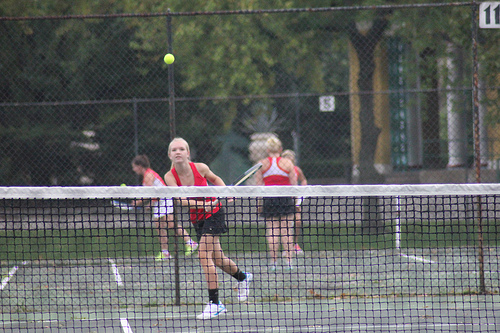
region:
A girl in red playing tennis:
[163, 136, 253, 319]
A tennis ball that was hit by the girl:
[162, 52, 174, 65]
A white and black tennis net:
[1, 182, 499, 332]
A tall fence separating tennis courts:
[2, 1, 499, 307]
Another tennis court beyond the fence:
[1, 243, 498, 308]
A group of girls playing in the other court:
[108, 135, 305, 272]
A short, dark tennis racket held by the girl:
[201, 165, 263, 213]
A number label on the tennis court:
[478, 1, 498, 29]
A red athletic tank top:
[169, 161, 223, 222]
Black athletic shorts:
[190, 205, 230, 241]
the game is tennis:
[9, 15, 488, 327]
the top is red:
[158, 161, 227, 217]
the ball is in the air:
[143, 45, 180, 72]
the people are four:
[122, 114, 324, 283]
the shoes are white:
[200, 268, 260, 327]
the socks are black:
[200, 271, 225, 303]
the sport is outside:
[5, 14, 482, 316]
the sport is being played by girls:
[134, 114, 324, 287]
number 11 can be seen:
[472, 7, 498, 23]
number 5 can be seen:
[312, 91, 344, 121]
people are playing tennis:
[108, 129, 308, 323]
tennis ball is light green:
[161, 50, 173, 64]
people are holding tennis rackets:
[109, 162, 266, 214]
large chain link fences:
[0, 0, 499, 307]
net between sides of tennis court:
[1, 182, 499, 332]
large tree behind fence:
[120, 1, 495, 233]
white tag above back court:
[318, 94, 335, 112]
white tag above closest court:
[479, 0, 499, 30]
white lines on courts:
[2, 249, 434, 331]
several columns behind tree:
[341, 25, 498, 183]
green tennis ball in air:
[162, 50, 179, 70]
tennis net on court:
[2, 185, 499, 330]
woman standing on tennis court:
[253, 135, 301, 272]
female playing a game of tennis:
[164, 138, 255, 317]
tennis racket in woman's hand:
[220, 158, 264, 208]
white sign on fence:
[477, 3, 498, 31]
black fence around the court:
[0, 15, 162, 100]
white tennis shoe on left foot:
[195, 302, 230, 322]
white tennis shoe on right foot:
[235, 270, 262, 306]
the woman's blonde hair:
[262, 138, 282, 155]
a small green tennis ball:
[160, 53, 177, 67]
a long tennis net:
[0, 183, 497, 332]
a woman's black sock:
[205, 285, 222, 307]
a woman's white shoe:
[193, 300, 228, 322]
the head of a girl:
[167, 135, 190, 163]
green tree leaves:
[175, 20, 327, 102]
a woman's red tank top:
[166, 160, 225, 217]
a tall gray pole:
[442, 45, 473, 163]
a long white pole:
[105, 255, 129, 289]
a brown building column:
[340, 35, 391, 165]